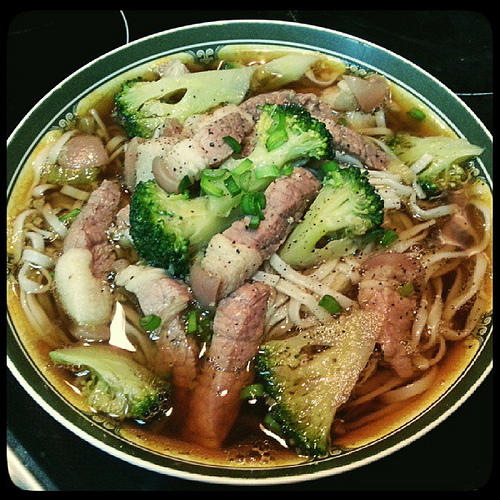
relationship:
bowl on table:
[4, 16, 492, 491] [428, 460, 483, 494]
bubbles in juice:
[227, 442, 273, 465] [143, 418, 185, 446]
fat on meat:
[204, 233, 253, 279] [227, 200, 297, 250]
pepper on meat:
[207, 136, 243, 161] [180, 135, 217, 161]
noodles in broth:
[37, 202, 68, 244] [10, 39, 475, 440]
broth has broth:
[5, 42, 495, 472] [240, 416, 285, 444]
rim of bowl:
[300, 370, 485, 479] [4, 13, 473, 483]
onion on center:
[337, 68, 390, 111] [218, 166, 268, 218]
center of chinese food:
[218, 166, 268, 218] [2, 46, 492, 474]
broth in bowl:
[5, 42, 495, 472] [4, 13, 473, 483]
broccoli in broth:
[46, 342, 172, 419] [5, 42, 495, 472]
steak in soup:
[186, 290, 280, 450] [13, 44, 498, 465]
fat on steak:
[201, 233, 262, 303] [182, 166, 327, 300]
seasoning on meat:
[102, 119, 371, 351] [50, 94, 448, 448]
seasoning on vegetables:
[102, 119, 371, 351] [64, 70, 413, 460]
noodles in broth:
[8, 141, 477, 415] [5, 42, 495, 472]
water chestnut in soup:
[52, 244, 124, 345] [13, 44, 498, 465]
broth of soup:
[121, 306, 488, 489] [13, 44, 498, 465]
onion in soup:
[337, 68, 390, 111] [13, 44, 498, 465]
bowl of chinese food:
[4, 13, 473, 483] [28, 46, 488, 449]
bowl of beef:
[4, 13, 473, 483] [37, 83, 453, 439]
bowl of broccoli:
[4, 13, 473, 483] [57, 68, 393, 455]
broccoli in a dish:
[46, 342, 172, 419] [6, 14, 496, 481]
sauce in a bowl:
[133, 379, 396, 479] [4, 13, 473, 483]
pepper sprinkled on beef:
[106, 84, 413, 378] [50, 86, 471, 464]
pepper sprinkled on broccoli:
[106, 84, 413, 378] [57, 68, 393, 455]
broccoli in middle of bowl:
[112, 73, 377, 271] [4, 13, 473, 483]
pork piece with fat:
[202, 165, 334, 305] [201, 233, 262, 303]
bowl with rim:
[4, 13, 473, 483] [10, 14, 495, 486]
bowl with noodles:
[4, 16, 492, 491] [30, 53, 497, 460]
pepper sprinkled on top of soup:
[99, 98, 371, 323] [13, 44, 498, 465]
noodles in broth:
[37, 202, 68, 244] [26, 60, 493, 474]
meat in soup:
[184, 278, 267, 456] [13, 44, 498, 465]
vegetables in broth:
[124, 173, 227, 269] [10, 39, 475, 440]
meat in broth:
[352, 249, 426, 379] [10, 39, 475, 440]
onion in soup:
[346, 71, 391, 111] [142, 53, 467, 203]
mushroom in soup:
[57, 127, 111, 179] [13, 44, 498, 465]